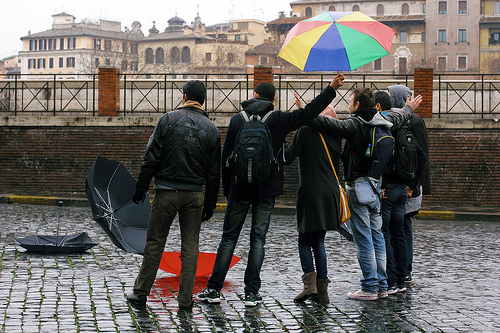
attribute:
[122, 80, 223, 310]
man — standing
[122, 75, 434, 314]
group — standing, together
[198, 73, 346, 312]
man — standing, young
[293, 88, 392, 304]
man — standing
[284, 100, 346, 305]
woman — standing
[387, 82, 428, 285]
man — standing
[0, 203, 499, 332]
road — wet, brick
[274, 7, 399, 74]
umbrella — multicolored, held, up, colorful, open, black, multi colored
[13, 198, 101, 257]
umbrella — flipped, black, upside down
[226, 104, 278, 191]
backpack — black, grey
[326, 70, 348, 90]
hand — aloft, held up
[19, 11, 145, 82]
building — large, historic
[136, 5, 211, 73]
building — large, historic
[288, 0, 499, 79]
building — large, historic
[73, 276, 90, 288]
cobblestone — wet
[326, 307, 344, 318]
cobblestone — wet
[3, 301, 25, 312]
cobblestone — wet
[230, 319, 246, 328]
cobblestone — wet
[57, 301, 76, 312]
cobblestone — wet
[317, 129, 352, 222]
sling bag — yellow, orange, brown, tan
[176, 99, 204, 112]
scarf — tan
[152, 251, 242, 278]
umbrella — upside down, red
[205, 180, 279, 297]
jeans — blue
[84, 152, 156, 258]
umbrella — black, pointing down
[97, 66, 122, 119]
fence support — brick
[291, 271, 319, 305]
boot — brown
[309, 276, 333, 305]
boot — brown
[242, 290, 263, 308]
shoe — black, white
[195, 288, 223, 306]
shoe — black, white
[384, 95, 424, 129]
arm — extended, out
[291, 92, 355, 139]
arm — extended, out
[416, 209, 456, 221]
paint — yellow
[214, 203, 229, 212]
paint — yellow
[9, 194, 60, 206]
paint — yellow